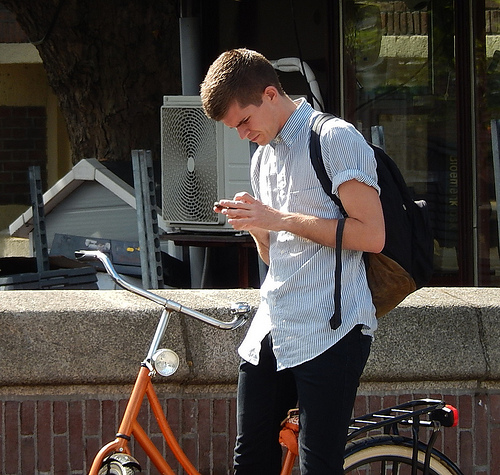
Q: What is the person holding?
A: Cell phone.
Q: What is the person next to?
A: Bicycle.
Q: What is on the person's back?
A: Backpack.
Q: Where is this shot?
A: Street.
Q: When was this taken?
A: Daytime.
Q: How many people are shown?
A: 1.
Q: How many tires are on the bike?
A: 2.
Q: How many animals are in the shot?
A: 0.